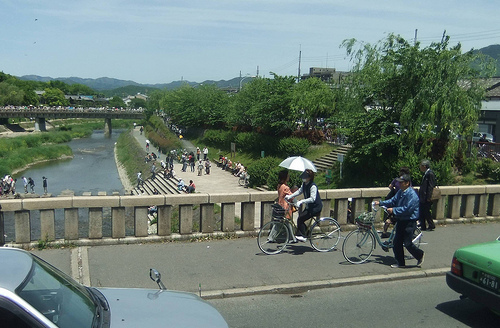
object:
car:
[444, 238, 499, 310]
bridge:
[0, 183, 499, 327]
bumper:
[445, 272, 499, 310]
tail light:
[450, 258, 463, 277]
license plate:
[476, 272, 499, 295]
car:
[0, 246, 230, 327]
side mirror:
[148, 270, 165, 287]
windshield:
[15, 253, 97, 327]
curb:
[194, 266, 451, 299]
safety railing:
[0, 183, 500, 250]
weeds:
[37, 232, 50, 251]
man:
[370, 175, 427, 269]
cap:
[393, 174, 415, 185]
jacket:
[379, 187, 421, 223]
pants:
[391, 220, 424, 265]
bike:
[342, 201, 425, 265]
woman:
[265, 169, 300, 243]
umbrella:
[277, 155, 318, 173]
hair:
[277, 169, 289, 183]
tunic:
[274, 182, 296, 220]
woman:
[282, 168, 324, 243]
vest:
[302, 182, 323, 213]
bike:
[257, 195, 342, 255]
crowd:
[194, 159, 206, 176]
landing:
[167, 160, 303, 231]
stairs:
[129, 168, 196, 225]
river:
[0, 127, 135, 242]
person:
[42, 176, 48, 195]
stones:
[82, 191, 91, 196]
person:
[27, 176, 36, 194]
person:
[20, 176, 28, 194]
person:
[9, 179, 17, 197]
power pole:
[297, 50, 302, 80]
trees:
[143, 71, 355, 144]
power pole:
[239, 68, 244, 90]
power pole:
[255, 67, 261, 78]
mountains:
[17, 76, 253, 95]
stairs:
[312, 142, 354, 173]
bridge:
[0, 103, 150, 135]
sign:
[335, 151, 344, 163]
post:
[339, 161, 344, 181]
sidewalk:
[0, 220, 500, 302]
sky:
[1, 1, 500, 85]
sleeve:
[295, 185, 318, 210]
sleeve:
[285, 183, 306, 198]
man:
[414, 160, 438, 231]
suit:
[417, 168, 436, 230]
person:
[137, 171, 145, 189]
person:
[185, 179, 195, 194]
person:
[149, 163, 157, 181]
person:
[176, 179, 183, 191]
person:
[153, 189, 160, 195]